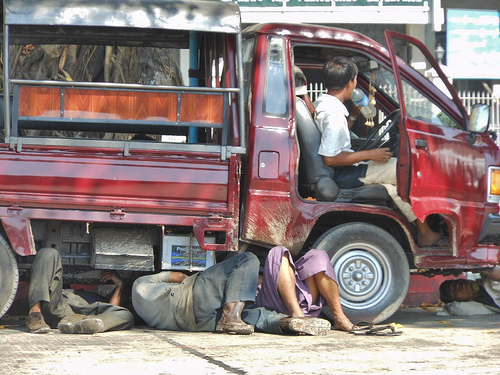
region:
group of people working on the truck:
[26, 242, 498, 344]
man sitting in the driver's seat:
[314, 59, 439, 251]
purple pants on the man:
[254, 247, 336, 319]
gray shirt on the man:
[131, 271, 203, 331]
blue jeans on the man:
[191, 255, 286, 333]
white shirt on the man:
[314, 97, 350, 162]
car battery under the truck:
[160, 235, 215, 275]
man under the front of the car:
[436, 268, 498, 320]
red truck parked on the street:
[0, 2, 495, 307]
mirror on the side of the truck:
[465, 102, 492, 138]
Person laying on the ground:
[17, 240, 127, 345]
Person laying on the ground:
[131, 262, 269, 344]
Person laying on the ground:
[259, 246, 344, 347]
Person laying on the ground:
[434, 262, 491, 327]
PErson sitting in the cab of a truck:
[314, 58, 439, 244]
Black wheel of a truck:
[315, 225, 402, 322]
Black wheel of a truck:
[2, 230, 35, 322]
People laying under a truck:
[29, 227, 494, 362]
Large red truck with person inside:
[2, 1, 499, 282]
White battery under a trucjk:
[157, 231, 252, 267]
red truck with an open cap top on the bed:
[8, 0, 498, 320]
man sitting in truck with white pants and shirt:
[312, 54, 451, 251]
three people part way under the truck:
[26, 240, 366, 338]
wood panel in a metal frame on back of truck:
[6, 80, 231, 133]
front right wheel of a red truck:
[308, 218, 411, 326]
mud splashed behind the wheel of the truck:
[243, 192, 310, 252]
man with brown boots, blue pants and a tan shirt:
[129, 250, 334, 343]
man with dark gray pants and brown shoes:
[25, 245, 134, 335]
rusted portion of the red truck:
[411, 260, 498, 273]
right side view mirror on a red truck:
[462, 103, 492, 142]